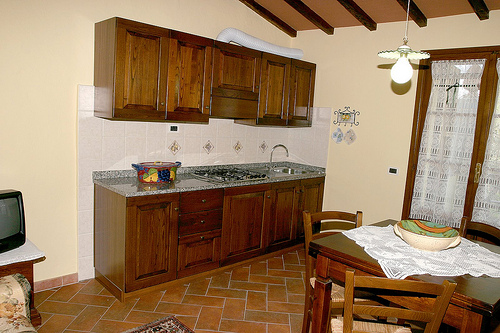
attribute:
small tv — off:
[0, 185, 29, 254]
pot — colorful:
[126, 157, 181, 186]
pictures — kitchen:
[0, 2, 499, 331]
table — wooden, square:
[296, 210, 500, 326]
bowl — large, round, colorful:
[385, 215, 469, 253]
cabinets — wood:
[92, 156, 329, 302]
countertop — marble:
[84, 154, 329, 199]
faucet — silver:
[270, 142, 290, 171]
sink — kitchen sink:
[258, 160, 307, 183]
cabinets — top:
[84, 12, 320, 140]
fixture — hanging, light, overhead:
[372, 1, 441, 106]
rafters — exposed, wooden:
[233, 1, 500, 43]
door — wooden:
[114, 18, 168, 127]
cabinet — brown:
[86, 14, 330, 309]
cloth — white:
[340, 217, 498, 309]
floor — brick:
[32, 242, 446, 332]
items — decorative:
[333, 100, 362, 148]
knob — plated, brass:
[472, 160, 484, 195]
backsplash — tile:
[75, 78, 339, 286]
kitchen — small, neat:
[0, 2, 498, 327]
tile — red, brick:
[21, 228, 455, 331]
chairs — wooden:
[296, 203, 499, 330]